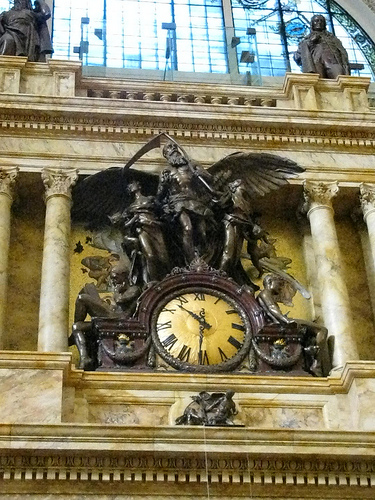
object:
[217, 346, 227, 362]
roman numeral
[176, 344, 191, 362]
roman numeral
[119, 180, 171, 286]
statue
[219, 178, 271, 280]
statue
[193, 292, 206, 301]
numeral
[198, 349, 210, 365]
numeral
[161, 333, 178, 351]
numeral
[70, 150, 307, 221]
wings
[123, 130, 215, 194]
tool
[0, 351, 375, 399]
ledge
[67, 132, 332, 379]
sculptures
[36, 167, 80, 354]
column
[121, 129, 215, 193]
scythe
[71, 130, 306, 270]
angel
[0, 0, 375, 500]
cathedral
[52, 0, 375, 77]
glass panels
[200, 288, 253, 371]
section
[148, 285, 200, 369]
section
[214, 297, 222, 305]
numeral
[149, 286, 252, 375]
clock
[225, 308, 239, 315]
numeral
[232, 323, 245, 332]
numeral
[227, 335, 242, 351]
numeral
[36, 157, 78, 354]
pillar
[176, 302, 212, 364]
hands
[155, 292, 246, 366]
face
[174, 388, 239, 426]
statue